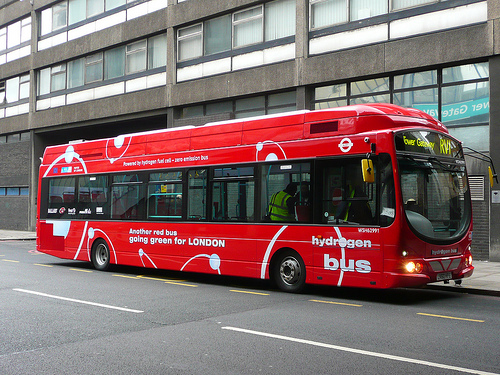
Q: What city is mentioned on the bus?
A: London.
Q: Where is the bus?
A: Street.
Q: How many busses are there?
A: One.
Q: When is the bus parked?
A: Daytime.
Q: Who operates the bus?
A: Driver.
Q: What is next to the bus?
A: Building.